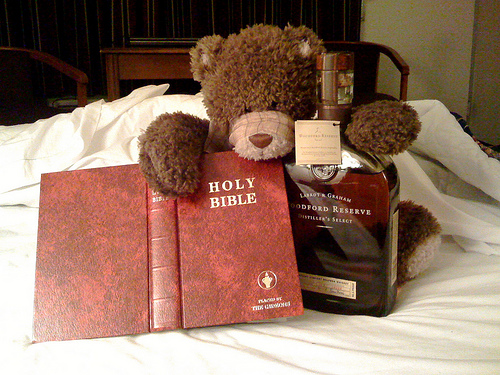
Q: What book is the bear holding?
A: A Bible.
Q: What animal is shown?
A: A bear.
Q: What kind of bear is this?
A: A teddy bear.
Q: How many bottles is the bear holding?
A: One.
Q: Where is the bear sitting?
A: On a bed.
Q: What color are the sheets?
A: White.